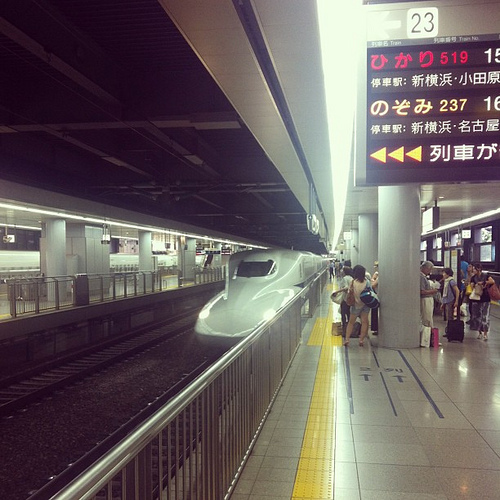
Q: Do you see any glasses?
A: No, there are no glasses.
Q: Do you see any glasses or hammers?
A: No, there are no glasses or hammers.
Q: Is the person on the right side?
A: Yes, the person is on the right of the image.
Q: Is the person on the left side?
A: No, the person is on the right of the image.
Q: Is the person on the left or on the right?
A: The person is on the right of the image.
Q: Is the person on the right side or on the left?
A: The person is on the right of the image.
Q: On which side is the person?
A: The person is on the right of the image.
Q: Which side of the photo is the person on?
A: The person is on the right of the image.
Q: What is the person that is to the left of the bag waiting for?
A: The person is waiting for the train.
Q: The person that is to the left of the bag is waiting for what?
A: The person is waiting for the train.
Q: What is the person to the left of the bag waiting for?
A: The person is waiting for the train.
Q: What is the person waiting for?
A: The person is waiting for the train.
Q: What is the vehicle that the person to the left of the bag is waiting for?
A: The vehicle is a train.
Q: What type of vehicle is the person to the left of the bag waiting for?
A: The person is waiting for the train.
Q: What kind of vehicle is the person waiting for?
A: The person is waiting for the train.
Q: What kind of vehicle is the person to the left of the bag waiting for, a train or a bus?
A: The person is waiting for a train.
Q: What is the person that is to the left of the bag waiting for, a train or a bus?
A: The person is waiting for a train.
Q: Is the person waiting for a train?
A: Yes, the person is waiting for a train.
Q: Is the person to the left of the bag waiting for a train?
A: Yes, the person is waiting for a train.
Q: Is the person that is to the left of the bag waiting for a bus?
A: No, the person is waiting for a train.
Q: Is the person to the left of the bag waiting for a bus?
A: No, the person is waiting for a train.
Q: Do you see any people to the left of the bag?
A: Yes, there is a person to the left of the bag.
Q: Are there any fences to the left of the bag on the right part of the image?
A: No, there is a person to the left of the bag.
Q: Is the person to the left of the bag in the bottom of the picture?
A: Yes, the person is to the left of the bag.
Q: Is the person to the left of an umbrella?
A: No, the person is to the left of the bag.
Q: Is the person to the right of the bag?
A: No, the person is to the left of the bag.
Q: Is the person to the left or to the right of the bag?
A: The person is to the left of the bag.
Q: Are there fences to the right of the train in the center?
A: No, there is a person to the right of the train.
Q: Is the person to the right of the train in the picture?
A: Yes, the person is to the right of the train.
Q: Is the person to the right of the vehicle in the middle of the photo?
A: Yes, the person is to the right of the train.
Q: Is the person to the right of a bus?
A: No, the person is to the right of the train.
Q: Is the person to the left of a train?
A: No, the person is to the right of a train.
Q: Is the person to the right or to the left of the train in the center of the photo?
A: The person is to the right of the train.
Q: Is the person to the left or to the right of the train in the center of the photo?
A: The person is to the right of the train.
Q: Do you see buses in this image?
A: No, there are no buses.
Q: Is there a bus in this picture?
A: No, there are no buses.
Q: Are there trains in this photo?
A: Yes, there is a train.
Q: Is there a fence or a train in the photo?
A: Yes, there is a train.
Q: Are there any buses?
A: No, there are no buses.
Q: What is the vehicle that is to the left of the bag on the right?
A: The vehicle is a train.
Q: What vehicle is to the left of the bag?
A: The vehicle is a train.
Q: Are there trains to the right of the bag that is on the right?
A: No, the train is to the left of the bag.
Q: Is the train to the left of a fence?
A: No, the train is to the left of the bag.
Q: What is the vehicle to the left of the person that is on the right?
A: The vehicle is a train.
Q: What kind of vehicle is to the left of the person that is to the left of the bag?
A: The vehicle is a train.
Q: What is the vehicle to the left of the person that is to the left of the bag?
A: The vehicle is a train.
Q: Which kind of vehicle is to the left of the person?
A: The vehicle is a train.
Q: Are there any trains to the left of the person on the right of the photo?
A: Yes, there is a train to the left of the person.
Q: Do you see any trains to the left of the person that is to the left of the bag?
A: Yes, there is a train to the left of the person.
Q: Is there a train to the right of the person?
A: No, the train is to the left of the person.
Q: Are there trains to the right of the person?
A: No, the train is to the left of the person.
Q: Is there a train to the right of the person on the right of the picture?
A: No, the train is to the left of the person.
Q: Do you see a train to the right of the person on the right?
A: No, the train is to the left of the person.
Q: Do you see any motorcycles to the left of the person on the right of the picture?
A: No, there is a train to the left of the person.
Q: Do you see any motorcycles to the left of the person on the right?
A: No, there is a train to the left of the person.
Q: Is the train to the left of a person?
A: Yes, the train is to the left of a person.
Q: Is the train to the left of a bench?
A: No, the train is to the left of a person.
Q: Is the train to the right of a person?
A: No, the train is to the left of a person.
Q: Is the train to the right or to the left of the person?
A: The train is to the left of the person.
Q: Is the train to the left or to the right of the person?
A: The train is to the left of the person.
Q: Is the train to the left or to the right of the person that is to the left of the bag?
A: The train is to the left of the person.